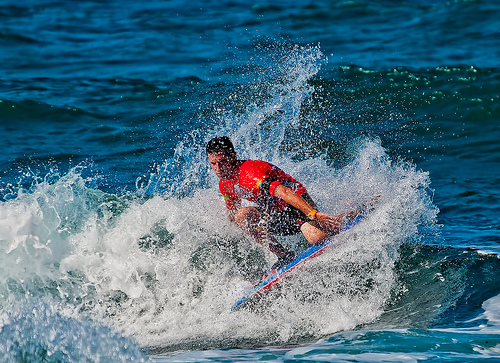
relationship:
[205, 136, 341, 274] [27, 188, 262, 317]
man riding a wave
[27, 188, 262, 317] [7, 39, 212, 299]
wave covered in sea foam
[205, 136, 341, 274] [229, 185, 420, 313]
man riding surfboard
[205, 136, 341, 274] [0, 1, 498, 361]
man in ocean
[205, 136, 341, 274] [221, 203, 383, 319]
man crouched on surfboard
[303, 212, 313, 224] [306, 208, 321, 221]
clock on left wrist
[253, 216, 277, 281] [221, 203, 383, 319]
thread above surfboard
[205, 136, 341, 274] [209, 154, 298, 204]
man has shirt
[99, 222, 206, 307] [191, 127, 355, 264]
splashes formed around surfer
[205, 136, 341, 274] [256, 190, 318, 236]
man wears black short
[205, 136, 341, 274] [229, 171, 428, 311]
man surfing on surfboard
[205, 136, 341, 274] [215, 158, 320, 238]
man wearing wetsuit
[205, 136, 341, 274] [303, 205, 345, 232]
man has hand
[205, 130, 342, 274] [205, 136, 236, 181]
man has head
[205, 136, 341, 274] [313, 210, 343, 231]
man has hand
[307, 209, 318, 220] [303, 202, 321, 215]
clock on left wrist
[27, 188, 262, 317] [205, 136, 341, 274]
wave around man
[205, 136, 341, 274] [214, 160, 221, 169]
man has nose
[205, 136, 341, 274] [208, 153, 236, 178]
man has face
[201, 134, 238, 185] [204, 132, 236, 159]
head has black hair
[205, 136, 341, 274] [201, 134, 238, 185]
man has head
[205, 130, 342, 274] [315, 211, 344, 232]
man has hand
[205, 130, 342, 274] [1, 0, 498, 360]
man in water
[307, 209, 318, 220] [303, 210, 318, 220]
clock on wrist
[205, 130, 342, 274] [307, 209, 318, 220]
man has clock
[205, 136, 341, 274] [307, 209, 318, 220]
man has clock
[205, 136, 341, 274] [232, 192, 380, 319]
man kneels on surfboard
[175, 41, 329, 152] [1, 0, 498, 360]
white spray on water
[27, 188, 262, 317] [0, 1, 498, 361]
wave on ocean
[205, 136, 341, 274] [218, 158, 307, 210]
man wears shirt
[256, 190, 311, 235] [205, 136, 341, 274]
black short on man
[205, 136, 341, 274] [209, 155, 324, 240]
man in wetsuit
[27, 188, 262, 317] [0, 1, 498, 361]
wave breaking on ocean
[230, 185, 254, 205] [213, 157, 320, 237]
design on wet suit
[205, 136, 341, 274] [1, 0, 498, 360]
man covered in water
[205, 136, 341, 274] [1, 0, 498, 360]
man surfing in water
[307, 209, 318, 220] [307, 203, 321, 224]
clock on wrist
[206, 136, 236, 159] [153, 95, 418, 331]
black hair on surfer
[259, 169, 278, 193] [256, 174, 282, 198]
stripe on sleeve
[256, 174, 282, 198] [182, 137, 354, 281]
sleeve of surfer'